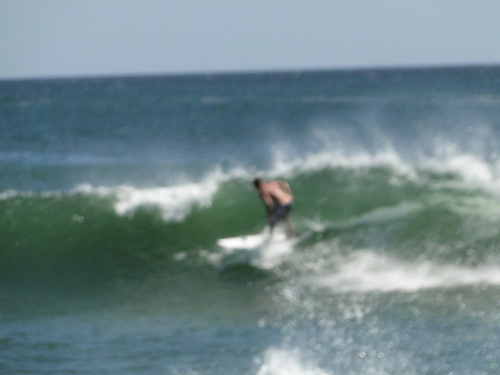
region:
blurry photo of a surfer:
[213, 153, 330, 275]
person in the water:
[218, 154, 338, 257]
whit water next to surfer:
[149, 168, 226, 233]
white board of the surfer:
[211, 216, 254, 273]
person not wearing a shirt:
[223, 163, 303, 246]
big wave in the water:
[327, 147, 412, 257]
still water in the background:
[92, 55, 167, 127]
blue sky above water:
[83, 15, 173, 58]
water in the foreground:
[105, 318, 194, 373]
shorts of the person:
[259, 196, 301, 234]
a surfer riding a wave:
[202, 170, 307, 271]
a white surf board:
[216, 235, 276, 252]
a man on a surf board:
[249, 169, 306, 237]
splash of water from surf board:
[205, 230, 370, 282]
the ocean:
[5, 76, 496, 363]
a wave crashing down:
[290, 145, 490, 260]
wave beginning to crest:
[16, 175, 216, 292]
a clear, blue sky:
[3, 2, 491, 62]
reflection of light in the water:
[261, 289, 342, 374]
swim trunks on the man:
[266, 197, 296, 228]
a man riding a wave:
[216, 177, 293, 250]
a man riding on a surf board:
[218, 176, 296, 250]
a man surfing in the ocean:
[215, 177, 296, 253]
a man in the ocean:
[216, 176, 301, 250]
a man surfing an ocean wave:
[215, 176, 294, 250]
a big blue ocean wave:
[1, 156, 496, 333]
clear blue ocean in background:
[0, 67, 495, 192]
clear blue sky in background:
[1, 3, 498, 78]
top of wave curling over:
[84, 148, 498, 238]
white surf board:
[217, 232, 305, 247]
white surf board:
[215, 226, 320, 263]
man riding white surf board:
[189, 157, 326, 299]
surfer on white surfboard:
[205, 168, 340, 280]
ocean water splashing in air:
[255, 283, 395, 373]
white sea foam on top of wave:
[113, 166, 211, 223]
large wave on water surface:
[5, 182, 107, 292]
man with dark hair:
[240, 168, 282, 207]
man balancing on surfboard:
[195, 158, 347, 289]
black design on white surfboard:
[236, 231, 249, 243]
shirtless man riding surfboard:
[175, 148, 368, 298]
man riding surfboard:
[214, 165, 324, 275]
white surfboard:
[218, 225, 275, 252]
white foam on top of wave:
[336, 256, 447, 291]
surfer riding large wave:
[143, 139, 401, 286]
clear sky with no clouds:
[100, 1, 449, 62]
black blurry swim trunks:
[264, 200, 295, 222]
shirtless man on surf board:
[177, 144, 335, 271]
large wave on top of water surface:
[7, 174, 214, 353]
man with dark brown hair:
[225, 163, 309, 279]